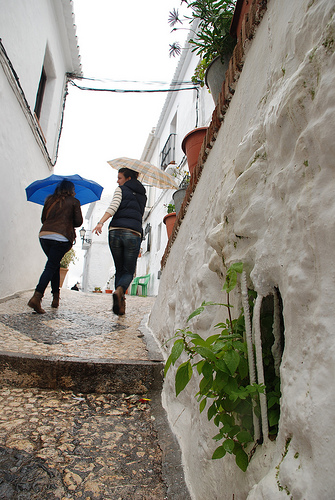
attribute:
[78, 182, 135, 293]
building — side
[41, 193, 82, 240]
jacket — brown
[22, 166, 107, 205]
umbrella — blue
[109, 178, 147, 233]
vest — blue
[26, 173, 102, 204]
umbrella — plaid, blue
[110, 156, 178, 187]
umbrella — plaid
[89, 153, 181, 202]
umbrella — orange, white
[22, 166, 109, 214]
umbrella — blue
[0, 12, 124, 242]
building — white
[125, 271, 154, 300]
chair — empty, green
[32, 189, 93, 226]
jacket — brown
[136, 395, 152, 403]
leaf — orange, yellow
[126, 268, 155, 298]
green chair — plastic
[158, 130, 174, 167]
balcony — black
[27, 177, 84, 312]
woman — walking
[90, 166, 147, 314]
woman — walking